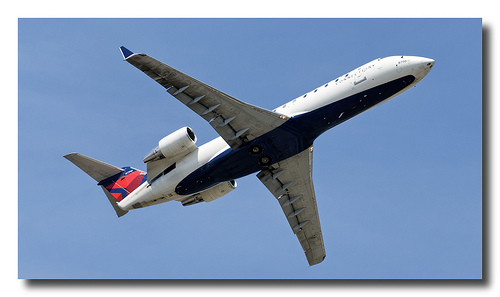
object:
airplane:
[63, 45, 435, 266]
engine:
[142, 126, 198, 164]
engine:
[181, 179, 238, 207]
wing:
[119, 45, 289, 149]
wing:
[256, 145, 327, 267]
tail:
[63, 151, 147, 218]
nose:
[391, 55, 435, 79]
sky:
[19, 18, 483, 280]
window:
[345, 74, 349, 78]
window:
[335, 79, 339, 82]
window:
[325, 84, 329, 87]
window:
[314, 89, 317, 93]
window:
[303, 94, 307, 97]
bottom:
[174, 74, 418, 196]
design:
[97, 166, 147, 202]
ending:
[181, 193, 205, 207]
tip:
[142, 145, 166, 164]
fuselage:
[116, 52, 436, 266]